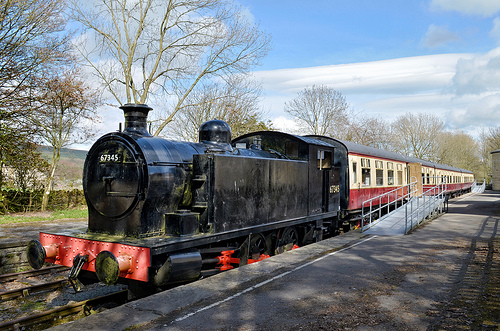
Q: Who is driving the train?
A: Conductor.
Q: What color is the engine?
A: Black and red.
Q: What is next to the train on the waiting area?
A: Ramp.